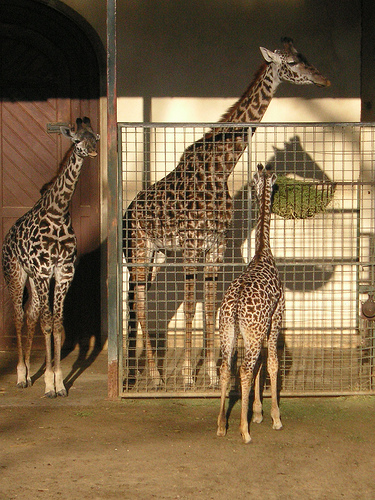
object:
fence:
[117, 122, 221, 398]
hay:
[279, 185, 305, 213]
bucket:
[271, 176, 335, 221]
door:
[0, 6, 103, 341]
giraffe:
[0, 115, 100, 397]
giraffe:
[213, 169, 287, 444]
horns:
[77, 113, 92, 135]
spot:
[42, 242, 56, 254]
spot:
[43, 202, 65, 220]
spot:
[261, 85, 273, 101]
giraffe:
[120, 35, 332, 390]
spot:
[243, 296, 260, 317]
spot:
[211, 154, 223, 174]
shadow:
[273, 136, 331, 183]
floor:
[74, 367, 104, 410]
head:
[273, 34, 331, 90]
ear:
[258, 43, 276, 65]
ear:
[269, 168, 279, 181]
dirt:
[28, 414, 117, 500]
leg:
[267, 333, 285, 431]